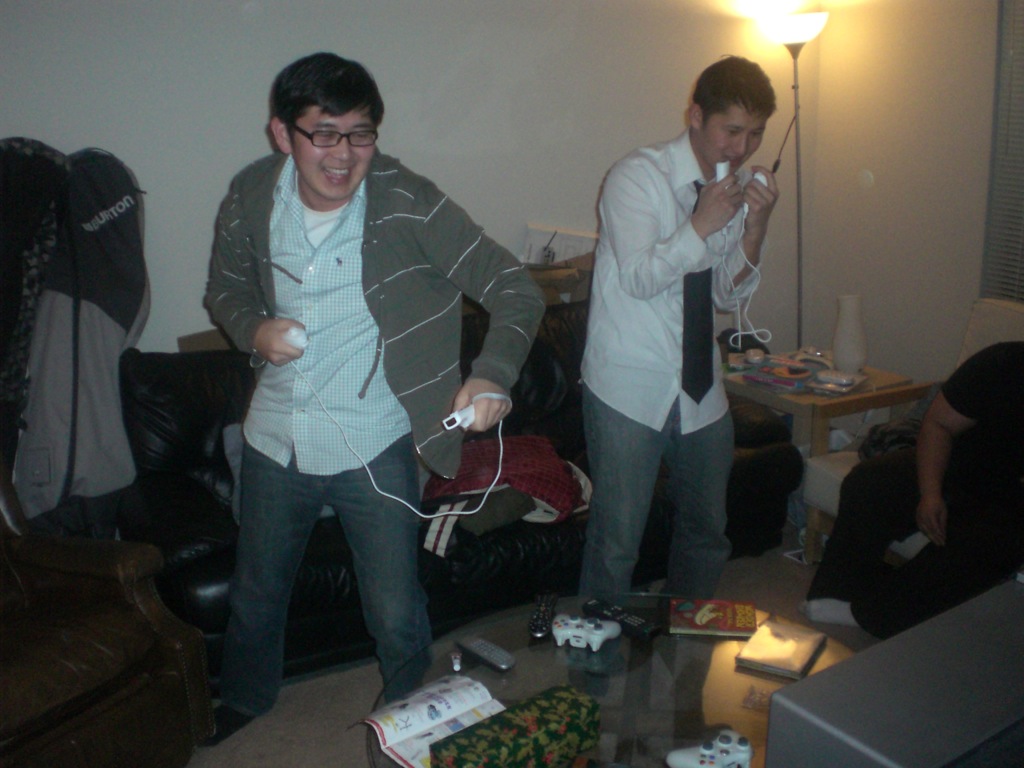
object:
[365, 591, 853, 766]
table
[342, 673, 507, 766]
paper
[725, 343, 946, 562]
table